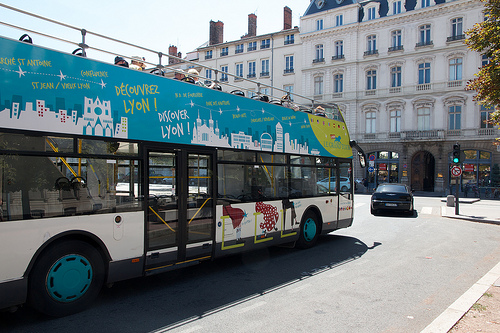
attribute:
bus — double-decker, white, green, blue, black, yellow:
[25, 26, 347, 286]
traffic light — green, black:
[448, 138, 460, 171]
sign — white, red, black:
[449, 165, 464, 181]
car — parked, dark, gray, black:
[370, 168, 418, 223]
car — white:
[321, 173, 354, 196]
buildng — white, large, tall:
[216, 6, 499, 146]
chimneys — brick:
[202, 13, 299, 35]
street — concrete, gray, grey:
[213, 207, 435, 333]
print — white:
[153, 106, 194, 141]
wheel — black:
[30, 239, 114, 317]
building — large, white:
[210, 21, 499, 185]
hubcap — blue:
[47, 258, 95, 305]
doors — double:
[128, 143, 232, 258]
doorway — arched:
[401, 144, 437, 202]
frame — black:
[138, 139, 218, 162]